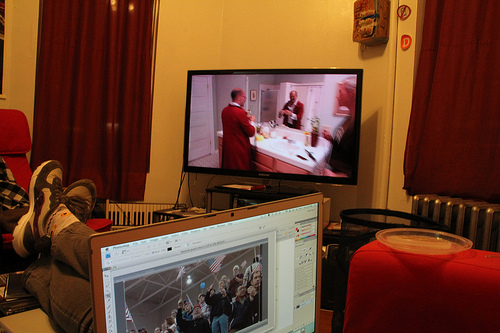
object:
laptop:
[88, 190, 325, 331]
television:
[184, 68, 364, 186]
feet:
[11, 156, 99, 257]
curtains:
[30, 1, 150, 203]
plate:
[376, 225, 475, 256]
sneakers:
[62, 179, 98, 218]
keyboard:
[94, 196, 186, 230]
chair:
[0, 109, 115, 255]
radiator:
[407, 195, 499, 253]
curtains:
[402, 2, 499, 202]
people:
[232, 265, 263, 329]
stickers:
[396, 6, 412, 21]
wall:
[9, 2, 426, 223]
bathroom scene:
[188, 73, 356, 178]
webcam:
[231, 213, 235, 217]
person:
[11, 159, 101, 331]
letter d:
[403, 38, 410, 48]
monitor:
[101, 202, 317, 331]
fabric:
[0, 157, 29, 232]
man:
[219, 89, 257, 172]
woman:
[321, 75, 357, 177]